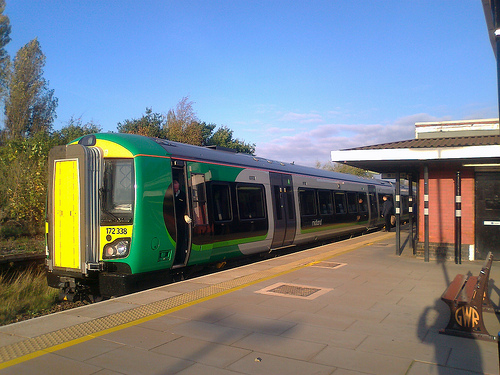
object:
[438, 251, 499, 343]
bench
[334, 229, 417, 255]
platform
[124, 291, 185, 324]
solid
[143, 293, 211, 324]
line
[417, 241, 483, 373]
shadow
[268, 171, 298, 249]
automatic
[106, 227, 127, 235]
number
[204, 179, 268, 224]
windows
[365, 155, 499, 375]
waiting area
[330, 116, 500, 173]
roof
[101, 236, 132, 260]
light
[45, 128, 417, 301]
back of train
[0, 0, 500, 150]
sky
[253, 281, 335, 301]
painted line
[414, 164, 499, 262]
boarding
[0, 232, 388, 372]
long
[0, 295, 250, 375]
stripe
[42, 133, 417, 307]
track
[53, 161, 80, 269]
yellow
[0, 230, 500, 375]
open area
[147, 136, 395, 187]
black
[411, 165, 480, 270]
poles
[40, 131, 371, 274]
train color is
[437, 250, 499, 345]
brown bench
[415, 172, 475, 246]
red wall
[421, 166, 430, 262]
black base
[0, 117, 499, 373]
at the station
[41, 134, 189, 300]
part